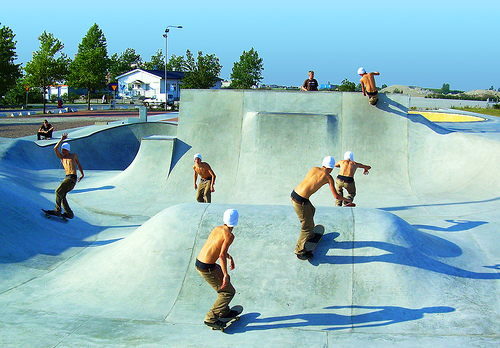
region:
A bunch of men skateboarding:
[20, 83, 432, 325]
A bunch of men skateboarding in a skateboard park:
[38, 86, 457, 311]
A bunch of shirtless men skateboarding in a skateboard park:
[46, 79, 459, 334]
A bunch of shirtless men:
[33, 118, 396, 316]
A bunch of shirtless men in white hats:
[44, 133, 356, 312]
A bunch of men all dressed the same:
[33, 129, 408, 318]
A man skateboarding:
[190, 198, 264, 346]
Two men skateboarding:
[282, 127, 373, 274]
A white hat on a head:
[215, 195, 245, 232]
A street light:
[151, 13, 190, 93]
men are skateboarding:
[51, 42, 484, 319]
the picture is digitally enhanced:
[46, 45, 446, 340]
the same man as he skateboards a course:
[58, 75, 454, 343]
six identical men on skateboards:
[53, 47, 440, 344]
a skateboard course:
[28, 34, 498, 346]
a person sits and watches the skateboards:
[21, 112, 73, 147]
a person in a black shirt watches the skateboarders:
[291, 62, 335, 114]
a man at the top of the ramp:
[298, 62, 340, 112]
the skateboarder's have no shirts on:
[49, 52, 469, 341]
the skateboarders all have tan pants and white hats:
[41, 36, 498, 338]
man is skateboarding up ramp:
[193, 196, 258, 338]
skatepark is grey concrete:
[118, 156, 365, 323]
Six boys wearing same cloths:
[39, 63, 401, 341]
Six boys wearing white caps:
[45, 66, 431, 337]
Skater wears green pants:
[187, 190, 267, 337]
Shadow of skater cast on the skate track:
[240, 278, 466, 340]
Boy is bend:
[185, 198, 258, 334]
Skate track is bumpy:
[10, 82, 497, 343]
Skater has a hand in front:
[35, 121, 95, 226]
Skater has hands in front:
[330, 146, 380, 208]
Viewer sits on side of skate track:
[30, 112, 58, 142]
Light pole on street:
[153, 14, 190, 113]